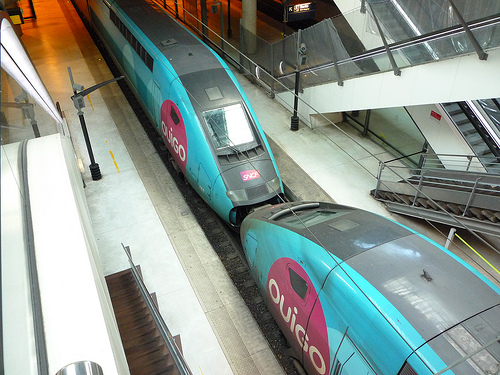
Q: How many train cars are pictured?
A: Two.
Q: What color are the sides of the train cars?
A: Bright blue.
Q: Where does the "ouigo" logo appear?
A: On the side of each train car.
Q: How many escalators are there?
A: Two.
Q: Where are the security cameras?
A: Hanging on the black poles on each side of the car in the background.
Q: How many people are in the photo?
A: None.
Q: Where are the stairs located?
A: On each side of the train in the foreground.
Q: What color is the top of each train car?
A: Grey.